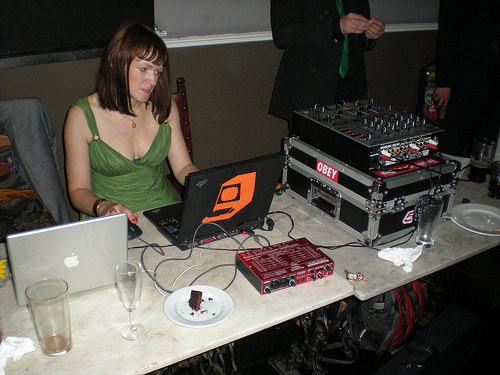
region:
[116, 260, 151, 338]
clear empty wine glass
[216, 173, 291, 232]
orange design on cover of laptop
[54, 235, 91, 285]
apple computer logo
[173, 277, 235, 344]
brown piece of cake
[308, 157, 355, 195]
red obey sticker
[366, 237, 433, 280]
white crumpled napkin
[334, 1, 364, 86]
green neck tie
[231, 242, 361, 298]
red and black electrical device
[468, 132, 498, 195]
clear glass with brown liquid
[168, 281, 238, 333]
white plate with cake on it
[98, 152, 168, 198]
women is wearing a green tank top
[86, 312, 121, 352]
the table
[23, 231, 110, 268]
Apple laptop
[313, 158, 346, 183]
an obey sticker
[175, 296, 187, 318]
a white plate on the table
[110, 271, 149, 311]
a wine glass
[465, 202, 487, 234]
a white plate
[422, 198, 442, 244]
a glass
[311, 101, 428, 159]
electronics equipment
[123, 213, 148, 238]
women is using a black mouse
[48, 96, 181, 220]
green tank top on woman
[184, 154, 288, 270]
black and orange laptop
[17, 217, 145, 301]
apple mac lap top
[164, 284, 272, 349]
plate with a piece of cake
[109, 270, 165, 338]
empty champagne glass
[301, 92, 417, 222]
sterio and audio system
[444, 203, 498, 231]
empty plate with crumbs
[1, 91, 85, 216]
gray mens suit jacket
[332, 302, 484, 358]
multiple wires together under table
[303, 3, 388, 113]
man wearing a green tie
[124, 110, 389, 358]
the laptop is black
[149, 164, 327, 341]
the laptop is black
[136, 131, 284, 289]
the laptop is black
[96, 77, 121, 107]
the woman has hair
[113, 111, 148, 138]
the woman wears a necklace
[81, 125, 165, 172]
the woman wears a green dress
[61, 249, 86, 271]
an apple is on the laptop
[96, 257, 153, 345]
the glass is empty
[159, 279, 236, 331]
a piece of food is on the plate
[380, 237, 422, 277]
a wadded up napkin is on the table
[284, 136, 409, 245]
the case is black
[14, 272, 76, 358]
the glass is big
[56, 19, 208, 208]
the woman is wearing a bracelet